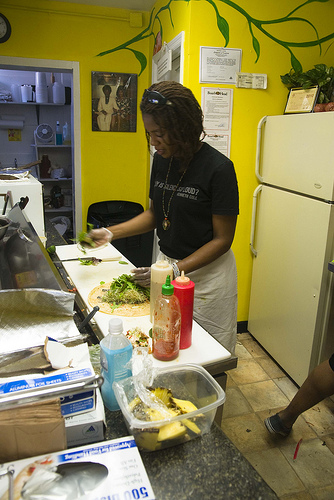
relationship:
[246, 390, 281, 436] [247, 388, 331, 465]
shoe on foot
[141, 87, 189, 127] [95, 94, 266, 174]
sunglasses on head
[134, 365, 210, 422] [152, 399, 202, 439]
container with pineapples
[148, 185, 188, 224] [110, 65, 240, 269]
necklace on woman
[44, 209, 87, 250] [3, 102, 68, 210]
fan on shelf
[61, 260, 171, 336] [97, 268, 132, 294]
tortilla with vegetables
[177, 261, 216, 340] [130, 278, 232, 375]
bottle has sauce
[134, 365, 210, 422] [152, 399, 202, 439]
container of pineapples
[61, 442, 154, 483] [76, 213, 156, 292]
box of gloves